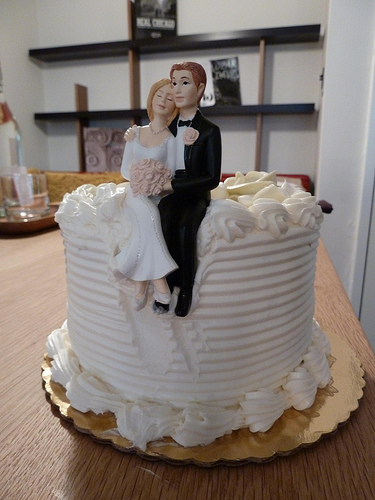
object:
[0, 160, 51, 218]
glass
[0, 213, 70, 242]
tray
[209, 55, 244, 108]
book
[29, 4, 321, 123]
shelf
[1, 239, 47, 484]
table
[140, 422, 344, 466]
foil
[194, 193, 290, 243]
artwork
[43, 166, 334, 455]
cake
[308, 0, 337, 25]
corner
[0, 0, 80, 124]
left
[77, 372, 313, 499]
shadows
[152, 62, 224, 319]
man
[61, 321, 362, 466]
frosting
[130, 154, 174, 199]
bouquet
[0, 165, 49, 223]
glasses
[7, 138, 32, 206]
bottle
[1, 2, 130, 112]
walls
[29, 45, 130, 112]
case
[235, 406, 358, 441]
stand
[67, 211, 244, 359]
frosting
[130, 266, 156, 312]
shoes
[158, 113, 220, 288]
tuxedo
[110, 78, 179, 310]
bride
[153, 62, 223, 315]
groom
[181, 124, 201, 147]
flower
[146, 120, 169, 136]
necklace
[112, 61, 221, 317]
doll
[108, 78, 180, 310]
woman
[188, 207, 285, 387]
icing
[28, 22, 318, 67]
shelves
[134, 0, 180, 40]
books